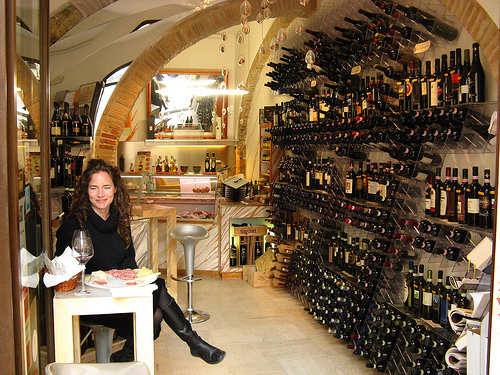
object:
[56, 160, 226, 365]
woman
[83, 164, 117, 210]
head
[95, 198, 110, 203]
mouth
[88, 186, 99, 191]
eye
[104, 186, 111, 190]
eye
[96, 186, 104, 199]
nose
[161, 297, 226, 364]
boot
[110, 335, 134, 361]
boot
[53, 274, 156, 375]
table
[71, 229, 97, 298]
wine glass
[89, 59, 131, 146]
window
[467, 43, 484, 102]
wine bottle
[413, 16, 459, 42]
wine bottle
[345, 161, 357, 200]
wine bottle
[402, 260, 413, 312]
wine bottle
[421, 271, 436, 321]
wine bottle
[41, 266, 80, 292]
basket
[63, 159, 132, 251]
hair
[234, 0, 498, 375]
wall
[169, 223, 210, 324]
stool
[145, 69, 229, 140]
mirror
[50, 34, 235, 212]
wall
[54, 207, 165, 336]
dress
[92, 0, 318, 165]
archway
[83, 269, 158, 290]
plate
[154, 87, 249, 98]
light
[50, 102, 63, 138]
wine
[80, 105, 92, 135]
wine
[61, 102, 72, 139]
wine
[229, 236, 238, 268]
wine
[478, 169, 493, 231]
wine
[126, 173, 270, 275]
deli counter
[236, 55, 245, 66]
drop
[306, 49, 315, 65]
drop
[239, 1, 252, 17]
drop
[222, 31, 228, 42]
drop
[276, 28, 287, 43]
drop